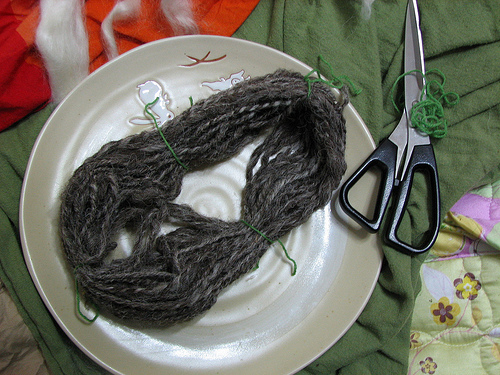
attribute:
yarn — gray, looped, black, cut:
[53, 73, 387, 324]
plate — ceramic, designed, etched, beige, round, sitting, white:
[20, 25, 435, 360]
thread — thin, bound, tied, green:
[142, 111, 207, 174]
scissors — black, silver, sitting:
[353, 1, 471, 267]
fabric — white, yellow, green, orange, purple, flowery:
[9, 4, 493, 370]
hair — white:
[36, 5, 211, 73]